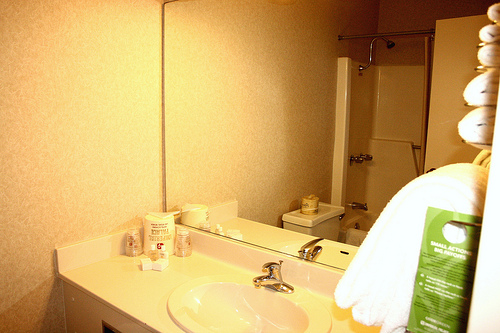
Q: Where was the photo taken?
A: Bathroom.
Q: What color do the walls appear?
A: Yellow.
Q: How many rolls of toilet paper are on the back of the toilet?
A: One.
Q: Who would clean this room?
A: Maid.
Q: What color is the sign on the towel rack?
A: Green.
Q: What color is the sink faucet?
A: Silver.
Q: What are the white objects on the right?
A: Towels.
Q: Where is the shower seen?
A: Mirror.